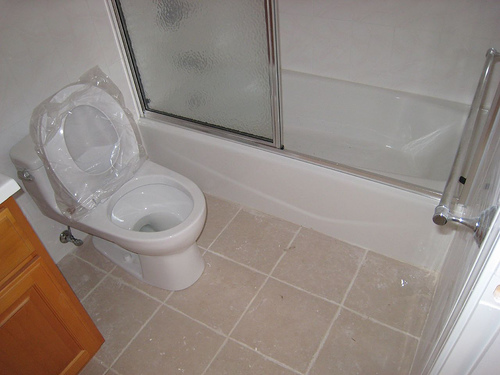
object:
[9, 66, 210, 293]
toilet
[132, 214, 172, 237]
water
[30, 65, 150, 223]
wrapping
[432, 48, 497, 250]
bar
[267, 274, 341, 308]
groove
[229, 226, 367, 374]
tiles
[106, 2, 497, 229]
shower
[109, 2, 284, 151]
door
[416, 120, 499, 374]
wall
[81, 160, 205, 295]
bowl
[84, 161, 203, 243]
edge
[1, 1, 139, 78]
wall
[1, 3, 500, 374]
bathroom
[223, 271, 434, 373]
floor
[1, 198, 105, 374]
cabinet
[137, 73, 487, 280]
bathtub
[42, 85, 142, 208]
lid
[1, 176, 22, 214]
corner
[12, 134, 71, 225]
water source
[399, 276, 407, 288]
debris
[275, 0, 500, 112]
tile